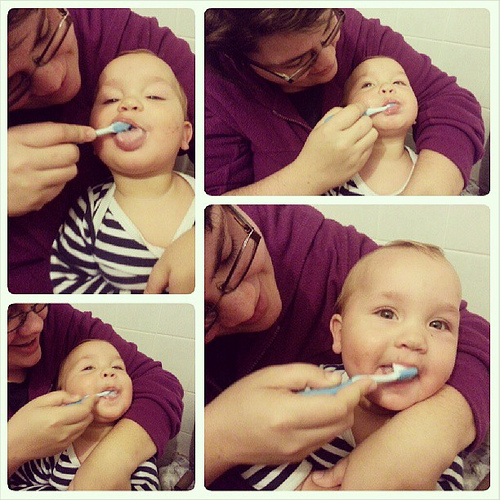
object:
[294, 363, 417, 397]
brush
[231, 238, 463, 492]
baby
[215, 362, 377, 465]
hand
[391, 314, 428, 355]
nose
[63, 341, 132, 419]
face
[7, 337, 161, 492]
baby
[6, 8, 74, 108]
glasses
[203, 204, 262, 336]
glasses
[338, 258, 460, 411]
face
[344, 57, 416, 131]
face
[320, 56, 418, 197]
boy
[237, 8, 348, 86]
spectacles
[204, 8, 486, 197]
woman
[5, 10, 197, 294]
woman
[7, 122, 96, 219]
hand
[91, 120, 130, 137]
toothbrush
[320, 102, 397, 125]
toothbrush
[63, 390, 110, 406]
toothbrush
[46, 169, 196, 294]
shirt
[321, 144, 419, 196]
shirt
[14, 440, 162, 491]
shirt